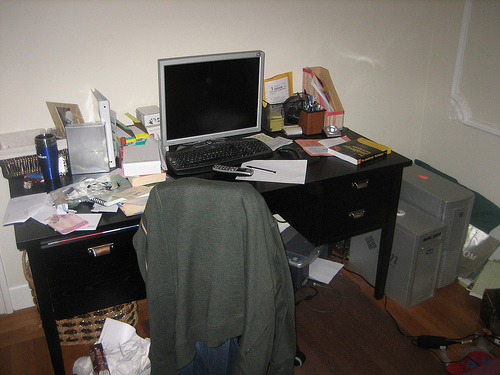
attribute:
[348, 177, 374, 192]
handle — metal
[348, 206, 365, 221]
handle — metal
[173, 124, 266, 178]
keyboard — black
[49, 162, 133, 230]
phone — tele, cordless, silver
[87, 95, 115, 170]
binder — white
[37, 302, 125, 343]
basket — brown, desk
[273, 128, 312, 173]
mouse — black, silver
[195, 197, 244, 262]
jacket — gra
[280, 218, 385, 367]
chair — coat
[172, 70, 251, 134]
screen — black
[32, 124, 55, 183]
mug — small, coffee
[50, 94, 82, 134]
frame — brown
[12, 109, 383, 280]
desk — messy, black, top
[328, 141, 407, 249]
drawer — small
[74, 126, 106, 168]
box — silver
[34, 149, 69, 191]
cup — blue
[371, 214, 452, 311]
tower — silver, short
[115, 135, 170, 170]
book — desk, black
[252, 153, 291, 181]
paper — white, bottom